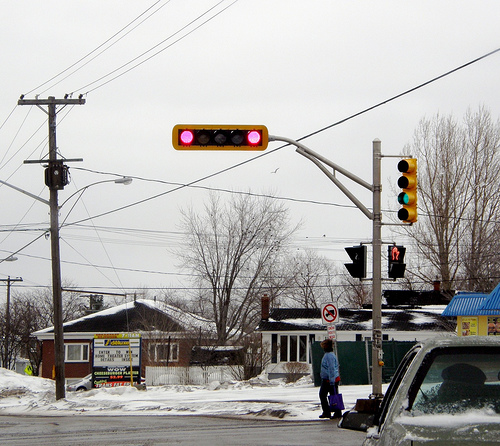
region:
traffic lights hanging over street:
[166, 115, 272, 165]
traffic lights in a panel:
[391, 142, 423, 228]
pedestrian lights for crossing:
[383, 238, 408, 280]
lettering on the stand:
[95, 349, 139, 362]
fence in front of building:
[143, 357, 246, 387]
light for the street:
[110, 170, 138, 193]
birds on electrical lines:
[206, 221, 333, 252]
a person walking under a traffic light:
[309, 328, 346, 420]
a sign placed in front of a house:
[91, 335, 171, 410]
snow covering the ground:
[148, 387, 230, 419]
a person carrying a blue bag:
[320, 367, 354, 419]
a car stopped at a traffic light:
[396, 322, 461, 437]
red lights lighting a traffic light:
[165, 124, 267, 161]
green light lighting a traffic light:
[391, 180, 422, 227]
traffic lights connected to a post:
[164, 122, 434, 244]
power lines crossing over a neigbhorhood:
[26, 177, 166, 295]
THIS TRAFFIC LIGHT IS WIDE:
[150, 113, 280, 164]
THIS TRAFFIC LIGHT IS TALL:
[392, 153, 422, 234]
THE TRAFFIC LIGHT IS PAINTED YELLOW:
[393, 150, 419, 231]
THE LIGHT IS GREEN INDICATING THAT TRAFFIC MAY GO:
[396, 191, 417, 204]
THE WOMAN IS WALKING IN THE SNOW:
[310, 332, 347, 420]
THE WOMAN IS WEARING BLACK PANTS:
[320, 372, 351, 423]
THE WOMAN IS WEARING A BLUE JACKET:
[315, 352, 350, 385]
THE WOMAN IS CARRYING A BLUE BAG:
[323, 390, 349, 415]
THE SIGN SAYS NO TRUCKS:
[322, 300, 340, 328]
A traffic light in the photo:
[155, 110, 296, 179]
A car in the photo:
[410, 340, 471, 440]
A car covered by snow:
[385, 330, 477, 437]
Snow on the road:
[155, 380, 250, 418]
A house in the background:
[96, 288, 186, 359]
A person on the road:
[300, 329, 368, 419]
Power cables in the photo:
[85, 20, 163, 157]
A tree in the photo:
[186, 217, 283, 327]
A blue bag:
[325, 381, 350, 413]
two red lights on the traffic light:
[160, 113, 287, 157]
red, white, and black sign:
[318, 300, 343, 324]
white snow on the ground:
[1, 361, 448, 428]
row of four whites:
[396, 153, 420, 232]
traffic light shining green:
[395, 190, 410, 205]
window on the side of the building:
[61, 340, 91, 362]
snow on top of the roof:
[42, 288, 242, 335]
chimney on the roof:
[255, 290, 273, 320]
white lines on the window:
[271, 331, 313, 364]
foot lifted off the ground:
[317, 412, 329, 421]